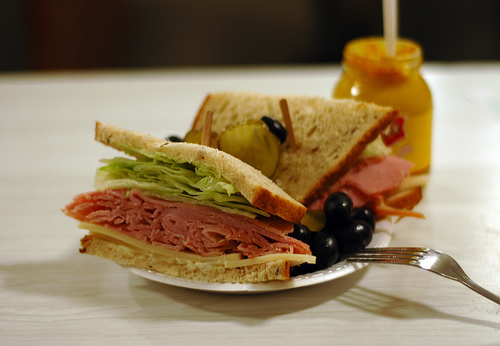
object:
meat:
[60, 187, 314, 258]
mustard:
[329, 35, 435, 190]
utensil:
[376, 0, 401, 57]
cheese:
[77, 221, 242, 265]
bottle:
[329, 37, 432, 198]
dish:
[120, 214, 394, 294]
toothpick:
[196, 110, 213, 147]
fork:
[346, 242, 499, 306]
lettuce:
[91, 142, 250, 207]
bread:
[89, 119, 306, 223]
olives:
[320, 190, 355, 221]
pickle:
[216, 116, 283, 177]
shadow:
[328, 283, 499, 330]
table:
[0, 61, 499, 345]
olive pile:
[286, 189, 376, 276]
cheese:
[223, 250, 317, 273]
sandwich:
[58, 119, 317, 286]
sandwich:
[182, 89, 432, 224]